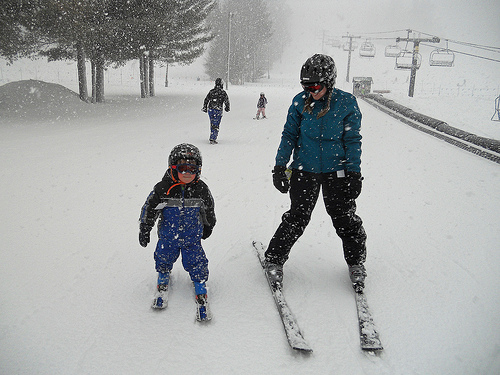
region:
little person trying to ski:
[147, 123, 247, 301]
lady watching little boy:
[271, 51, 423, 343]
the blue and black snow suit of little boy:
[128, 145, 242, 325]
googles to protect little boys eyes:
[166, 153, 206, 183]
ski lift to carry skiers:
[347, 28, 474, 140]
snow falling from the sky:
[15, 60, 140, 225]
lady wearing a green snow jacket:
[279, 73, 381, 205]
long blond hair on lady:
[294, 77, 355, 141]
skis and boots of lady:
[249, 223, 409, 373]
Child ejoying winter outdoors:
[132, 138, 222, 330]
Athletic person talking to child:
[259, 53, 379, 299]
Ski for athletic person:
[272, 298, 312, 356]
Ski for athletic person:
[351, 298, 393, 358]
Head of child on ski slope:
[165, 143, 203, 182]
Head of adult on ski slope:
[301, 53, 341, 105]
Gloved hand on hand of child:
[136, 231, 148, 246]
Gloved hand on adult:
[271, 166, 293, 198]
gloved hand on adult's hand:
[342, 172, 364, 204]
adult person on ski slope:
[203, 75, 238, 145]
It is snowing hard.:
[48, 19, 466, 369]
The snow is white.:
[28, 148, 103, 280]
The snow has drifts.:
[2, 60, 97, 151]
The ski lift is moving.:
[323, 12, 470, 71]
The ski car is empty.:
[426, 29, 456, 74]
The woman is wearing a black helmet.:
[281, 48, 353, 100]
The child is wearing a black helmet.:
[153, 138, 216, 179]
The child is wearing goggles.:
[160, 157, 205, 179]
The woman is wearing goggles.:
[289, 76, 336, 93]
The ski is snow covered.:
[243, 237, 313, 353]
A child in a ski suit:
[137, 142, 218, 325]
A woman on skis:
[251, 50, 386, 355]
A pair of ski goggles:
[298, 80, 327, 90]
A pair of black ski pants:
[267, 167, 366, 263]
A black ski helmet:
[169, 142, 202, 184]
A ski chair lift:
[310, 27, 497, 118]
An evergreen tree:
[202, 2, 277, 87]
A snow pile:
[3, 78, 83, 111]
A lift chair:
[397, 49, 422, 70]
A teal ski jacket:
[275, 87, 362, 176]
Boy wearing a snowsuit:
[138, 142, 216, 291]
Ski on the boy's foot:
[186, 285, 222, 327]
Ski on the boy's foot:
[148, 273, 174, 316]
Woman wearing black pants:
[261, 55, 375, 291]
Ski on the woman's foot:
[245, 225, 313, 360]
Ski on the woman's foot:
[330, 249, 389, 358]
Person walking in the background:
[197, 79, 237, 144]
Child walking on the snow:
[247, 89, 275, 121]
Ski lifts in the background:
[386, 36, 457, 81]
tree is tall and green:
[81, 0, 146, 104]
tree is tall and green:
[114, 0, 216, 96]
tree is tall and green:
[207, 5, 266, 84]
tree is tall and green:
[244, 1, 284, 84]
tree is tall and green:
[144, 6, 195, 101]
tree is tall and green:
[136, 7, 192, 99]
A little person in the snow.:
[154, 143, 221, 329]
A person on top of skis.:
[266, 50, 378, 357]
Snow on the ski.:
[266, 278, 322, 354]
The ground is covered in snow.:
[13, 124, 468, 374]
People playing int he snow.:
[186, 69, 290, 127]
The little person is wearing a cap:
[161, 138, 205, 165]